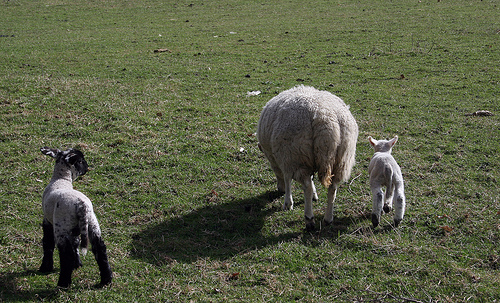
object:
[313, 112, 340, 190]
lamb tail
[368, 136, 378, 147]
ears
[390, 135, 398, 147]
ears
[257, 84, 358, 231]
animal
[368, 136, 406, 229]
animal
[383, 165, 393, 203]
tail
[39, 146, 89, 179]
head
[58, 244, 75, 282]
lamb leg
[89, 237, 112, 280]
lamb leg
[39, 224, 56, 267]
lamb leg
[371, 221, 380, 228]
feet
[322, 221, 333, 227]
feet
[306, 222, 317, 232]
feet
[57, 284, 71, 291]
feet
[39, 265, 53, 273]
feet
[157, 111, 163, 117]
leaf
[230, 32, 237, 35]
leaf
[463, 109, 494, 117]
leaf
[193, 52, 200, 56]
leaf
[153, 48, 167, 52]
leaf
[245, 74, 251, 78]
leaf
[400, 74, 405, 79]
leaf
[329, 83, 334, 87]
leaf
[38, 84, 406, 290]
three sheep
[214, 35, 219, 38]
leaf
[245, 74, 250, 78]
leaf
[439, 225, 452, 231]
leaf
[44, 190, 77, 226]
wool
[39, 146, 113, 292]
animals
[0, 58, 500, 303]
foreground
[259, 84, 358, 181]
wool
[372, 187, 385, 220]
legs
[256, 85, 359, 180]
fur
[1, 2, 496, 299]
grass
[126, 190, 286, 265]
shadow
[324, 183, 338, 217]
leg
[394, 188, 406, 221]
leg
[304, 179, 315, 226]
leg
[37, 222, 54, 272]
fur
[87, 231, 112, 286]
fur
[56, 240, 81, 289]
fur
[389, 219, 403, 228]
foot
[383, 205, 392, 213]
foot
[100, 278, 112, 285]
foot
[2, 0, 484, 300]
field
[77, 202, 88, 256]
tail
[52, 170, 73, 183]
neck